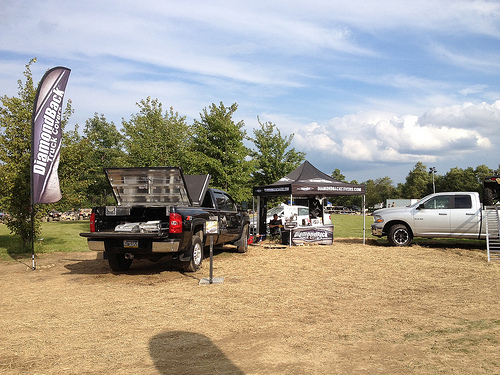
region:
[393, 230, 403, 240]
front wheel of a car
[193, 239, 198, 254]
back wheel of a truck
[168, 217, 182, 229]
back light of a truck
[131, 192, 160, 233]
back of a truck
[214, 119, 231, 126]
leaves of a tall tree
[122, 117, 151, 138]
branches of a tree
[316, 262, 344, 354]
brown surface of field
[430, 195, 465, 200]
window of a screen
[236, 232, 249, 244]
front wheel of a truck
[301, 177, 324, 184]
upper part of a tent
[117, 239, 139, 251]
The license plate on the black pick up truck.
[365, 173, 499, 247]
The silver colored pick up truck parked on the dirt.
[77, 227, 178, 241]
The opened tail gate of the black pick up truck.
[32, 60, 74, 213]
The diamond back banner on the pole.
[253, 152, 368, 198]
The black canopy of the stand.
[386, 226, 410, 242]
The front tire of the silver pickup.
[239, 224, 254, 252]
The front tire of the black pick up truck.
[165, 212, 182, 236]
The right red brake light on the black pickup.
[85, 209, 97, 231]
The left brake light of the black pick up.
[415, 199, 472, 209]
The driver side windows on the gray pick up truck.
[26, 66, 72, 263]
a banner standing next to the tree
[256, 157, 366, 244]
a covering for people sitting out at the park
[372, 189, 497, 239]
a silver truck sitting next to the tent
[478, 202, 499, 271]
a ladder sticking on the side of the truck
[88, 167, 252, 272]
a black truck sitting next to the tent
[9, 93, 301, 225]
a line of trees on the side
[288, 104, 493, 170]
a group of clouds on the side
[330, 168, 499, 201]
another line of trees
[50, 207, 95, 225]
people at the park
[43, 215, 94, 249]
a patch of grass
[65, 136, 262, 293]
very nice black pick up truck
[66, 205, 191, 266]
tail lights on a black truck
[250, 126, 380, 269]
black display tent with white letters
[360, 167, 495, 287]
nice white pick up truck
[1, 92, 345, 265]
several green trees blowing in the wind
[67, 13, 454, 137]
beautiful blue skys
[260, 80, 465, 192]
large beautiful fluffy white clouds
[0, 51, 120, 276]
black and white wind sign with the letter D on it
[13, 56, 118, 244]
wind sign with the letter i on it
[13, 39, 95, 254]
wind sign with the letter a on it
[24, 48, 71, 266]
diamond back truck cover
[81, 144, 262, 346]
a black truck parked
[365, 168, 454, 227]
trees in the background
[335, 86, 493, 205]
clouds in the sky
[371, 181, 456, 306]
silver ram truck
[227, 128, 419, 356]
tent set up in ground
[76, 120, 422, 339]
two trucks in the pic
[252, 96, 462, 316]
a park in background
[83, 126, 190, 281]
reflection is showing here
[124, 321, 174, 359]
shadow cast by sun